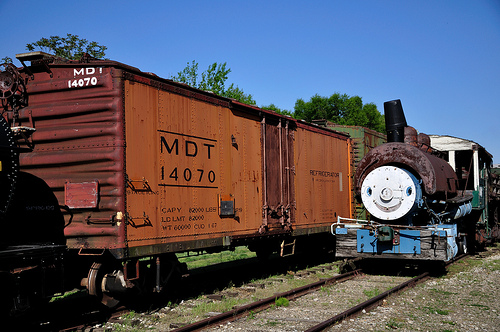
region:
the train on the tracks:
[330, 93, 492, 274]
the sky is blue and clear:
[60, 4, 490, 86]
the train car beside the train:
[23, 50, 362, 265]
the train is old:
[330, 112, 477, 273]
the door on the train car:
[256, 120, 303, 231]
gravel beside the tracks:
[388, 299, 483, 329]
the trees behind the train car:
[269, 86, 382, 121]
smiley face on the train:
[361, 166, 421, 223]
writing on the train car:
[150, 113, 222, 200]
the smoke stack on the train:
[367, 88, 429, 149]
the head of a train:
[363, 125, 488, 262]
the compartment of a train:
[58, 63, 338, 246]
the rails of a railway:
[263, 287, 359, 330]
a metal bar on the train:
[261, 118, 272, 223]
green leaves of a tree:
[292, 97, 381, 122]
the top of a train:
[96, 56, 295, 127]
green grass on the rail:
[272, 297, 290, 305]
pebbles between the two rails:
[272, 307, 317, 328]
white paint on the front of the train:
[371, 172, 399, 187]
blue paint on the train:
[358, 231, 373, 248]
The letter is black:
[156, 127, 181, 159]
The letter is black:
[181, 133, 198, 165]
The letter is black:
[200, 133, 217, 167]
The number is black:
[156, 162, 168, 184]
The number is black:
[165, 160, 182, 187]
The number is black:
[180, 163, 195, 185]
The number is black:
[193, 163, 205, 188]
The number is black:
[204, 164, 219, 187]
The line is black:
[157, 121, 221, 146]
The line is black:
[157, 175, 222, 196]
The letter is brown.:
[201, 139, 219, 161]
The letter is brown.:
[181, 135, 203, 160]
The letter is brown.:
[153, 131, 183, 162]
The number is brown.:
[153, 162, 169, 186]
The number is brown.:
[165, 161, 182, 186]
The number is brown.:
[179, 161, 196, 183]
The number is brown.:
[191, 162, 207, 187]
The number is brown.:
[206, 165, 225, 187]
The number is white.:
[70, 75, 79, 90]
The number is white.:
[82, 75, 92, 87]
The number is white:
[63, 76, 73, 89]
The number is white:
[67, 74, 79, 88]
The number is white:
[75, 74, 86, 89]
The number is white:
[81, 71, 90, 88]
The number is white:
[87, 75, 98, 87]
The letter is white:
[66, 65, 86, 78]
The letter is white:
[80, 60, 95, 78]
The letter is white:
[96, 63, 103, 75]